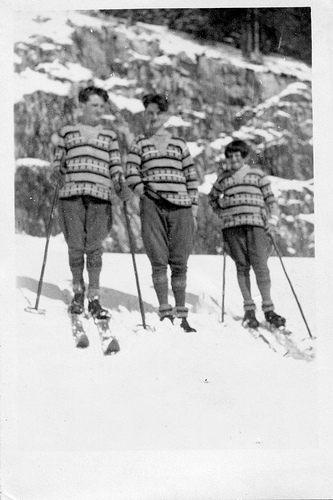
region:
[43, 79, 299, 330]
three people on the snow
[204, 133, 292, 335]
woman has black short hair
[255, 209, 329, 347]
pole on left hand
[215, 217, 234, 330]
pole on right hand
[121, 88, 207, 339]
a man in the middle of two people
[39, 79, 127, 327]
man on left side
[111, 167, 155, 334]
a snow pole on the right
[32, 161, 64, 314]
a snow pole on the left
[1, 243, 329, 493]
field is cover of snow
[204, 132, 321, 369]
man wearing skis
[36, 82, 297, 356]
three kids wearing matching outfits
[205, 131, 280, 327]
a girl with short hair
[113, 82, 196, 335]
a boy with his hand in his pocket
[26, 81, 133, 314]
a boy holding ski poles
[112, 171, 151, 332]
a ski pole held in a gloved hand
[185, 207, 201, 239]
a bare hand hanging down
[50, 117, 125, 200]
a sweater on a boy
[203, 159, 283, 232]
a sweater on a girl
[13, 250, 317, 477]
a white snowy slope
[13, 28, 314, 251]
a rocky cliff behind three kids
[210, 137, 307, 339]
girl standing on skis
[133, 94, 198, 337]
man standing in snow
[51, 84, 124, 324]
man standing on skis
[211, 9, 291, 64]
tree on snow covered hill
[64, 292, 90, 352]
long dark ski in snow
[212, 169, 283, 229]
patterned heavy winter sweater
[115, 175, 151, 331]
metal pole for skiing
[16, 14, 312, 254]
snow covered rock formation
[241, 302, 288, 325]
black snow boots on skis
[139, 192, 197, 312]
baggy winter ski pants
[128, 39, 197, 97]
the stone is filled with snow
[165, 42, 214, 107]
the stone is filled with snow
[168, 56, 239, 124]
the stone is filled with snow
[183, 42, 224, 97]
the stone is filled with snow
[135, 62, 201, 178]
the stone is filled with snow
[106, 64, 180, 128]
the stone is filled with snow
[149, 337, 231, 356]
an area of snow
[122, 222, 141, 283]
a long ski pole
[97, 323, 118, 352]
a ski in snow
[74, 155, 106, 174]
part of man's sweater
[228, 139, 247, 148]
hair on female skier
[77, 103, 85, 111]
an ear on skier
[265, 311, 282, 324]
shoe on skier's foot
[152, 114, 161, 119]
nose on the skier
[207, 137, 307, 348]
a skier on slope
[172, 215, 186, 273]
part of pants on skier